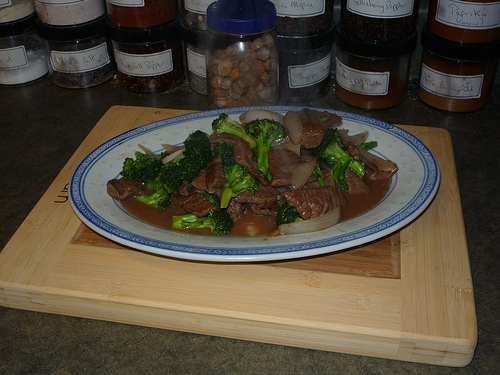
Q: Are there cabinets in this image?
A: No, there are no cabinets.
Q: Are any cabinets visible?
A: No, there are no cabinets.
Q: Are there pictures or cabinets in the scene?
A: No, there are no cabinets or pictures.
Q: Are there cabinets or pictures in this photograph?
A: No, there are no cabinets or pictures.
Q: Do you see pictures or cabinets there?
A: No, there are no cabinets or pictures.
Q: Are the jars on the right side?
A: Yes, the jars are on the right of the image.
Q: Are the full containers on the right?
A: Yes, the jars are on the right of the image.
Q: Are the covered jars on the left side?
A: No, the jars are on the right of the image.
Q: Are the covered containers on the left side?
A: No, the jars are on the right of the image.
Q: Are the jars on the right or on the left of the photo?
A: The jars are on the right of the image.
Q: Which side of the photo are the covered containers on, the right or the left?
A: The jars are on the right of the image.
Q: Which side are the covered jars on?
A: The jars are on the right of the image.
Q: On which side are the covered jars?
A: The jars are on the right of the image.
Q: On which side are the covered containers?
A: The jars are on the right of the image.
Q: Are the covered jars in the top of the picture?
A: Yes, the jars are in the top of the image.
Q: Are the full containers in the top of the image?
A: Yes, the jars are in the top of the image.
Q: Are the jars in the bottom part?
A: No, the jars are in the top of the image.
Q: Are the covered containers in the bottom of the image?
A: No, the jars are in the top of the image.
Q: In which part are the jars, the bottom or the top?
A: The jars are in the top of the image.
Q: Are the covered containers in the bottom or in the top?
A: The jars are in the top of the image.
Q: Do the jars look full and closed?
A: Yes, the jars are full and closed.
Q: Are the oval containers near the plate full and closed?
A: Yes, the jars are full and closed.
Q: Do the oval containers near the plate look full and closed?
A: Yes, the jars are full and closed.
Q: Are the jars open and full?
A: No, the jars are full but closed.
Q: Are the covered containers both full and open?
A: No, the jars are full but closed.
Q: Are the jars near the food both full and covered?
A: Yes, the jars are full and covered.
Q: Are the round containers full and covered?
A: Yes, the jars are full and covered.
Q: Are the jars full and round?
A: Yes, the jars are full and round.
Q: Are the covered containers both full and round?
A: Yes, the jars are full and round.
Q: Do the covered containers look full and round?
A: Yes, the jars are full and round.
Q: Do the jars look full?
A: Yes, the jars are full.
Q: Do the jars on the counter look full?
A: Yes, the jars are full.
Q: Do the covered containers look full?
A: Yes, the jars are full.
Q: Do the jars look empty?
A: No, the jars are full.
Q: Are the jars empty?
A: No, the jars are full.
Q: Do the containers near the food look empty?
A: No, the jars are full.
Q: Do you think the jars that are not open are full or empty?
A: The jars are full.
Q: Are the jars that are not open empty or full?
A: The jars are full.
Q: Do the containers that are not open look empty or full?
A: The jars are full.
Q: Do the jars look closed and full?
A: Yes, the jars are closed and full.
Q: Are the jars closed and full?
A: Yes, the jars are closed and full.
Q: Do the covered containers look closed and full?
A: Yes, the jars are closed and full.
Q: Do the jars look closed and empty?
A: No, the jars are closed but full.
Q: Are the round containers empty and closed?
A: No, the jars are closed but full.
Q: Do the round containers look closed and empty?
A: No, the jars are closed but full.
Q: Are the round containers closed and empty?
A: No, the jars are closed but full.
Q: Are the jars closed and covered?
A: Yes, the jars are closed and covered.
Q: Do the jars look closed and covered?
A: Yes, the jars are closed and covered.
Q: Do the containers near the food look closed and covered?
A: Yes, the jars are closed and covered.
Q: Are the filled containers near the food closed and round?
A: Yes, the jars are closed and round.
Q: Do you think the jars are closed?
A: Yes, the jars are closed.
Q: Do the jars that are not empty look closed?
A: Yes, the jars are closed.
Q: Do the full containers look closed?
A: Yes, the jars are closed.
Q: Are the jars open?
A: No, the jars are closed.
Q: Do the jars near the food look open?
A: No, the jars are closed.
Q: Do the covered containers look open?
A: No, the jars are closed.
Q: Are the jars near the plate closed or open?
A: The jars are closed.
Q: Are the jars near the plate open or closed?
A: The jars are closed.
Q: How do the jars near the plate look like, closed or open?
A: The jars are closed.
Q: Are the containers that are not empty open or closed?
A: The jars are closed.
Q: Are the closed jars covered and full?
A: Yes, the jars are covered and full.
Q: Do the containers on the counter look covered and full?
A: Yes, the jars are covered and full.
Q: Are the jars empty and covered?
A: No, the jars are covered but full.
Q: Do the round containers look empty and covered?
A: No, the jars are covered but full.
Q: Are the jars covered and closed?
A: Yes, the jars are covered and closed.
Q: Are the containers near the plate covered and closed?
A: Yes, the jars are covered and closed.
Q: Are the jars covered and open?
A: No, the jars are covered but closed.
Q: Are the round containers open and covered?
A: No, the jars are covered but closed.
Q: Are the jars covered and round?
A: Yes, the jars are covered and round.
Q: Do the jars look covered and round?
A: Yes, the jars are covered and round.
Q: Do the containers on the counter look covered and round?
A: Yes, the jars are covered and round.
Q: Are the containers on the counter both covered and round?
A: Yes, the jars are covered and round.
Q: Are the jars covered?
A: Yes, the jars are covered.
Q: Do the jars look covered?
A: Yes, the jars are covered.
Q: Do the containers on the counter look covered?
A: Yes, the jars are covered.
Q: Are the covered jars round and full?
A: Yes, the jars are round and full.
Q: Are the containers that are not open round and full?
A: Yes, the jars are round and full.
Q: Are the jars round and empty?
A: No, the jars are round but full.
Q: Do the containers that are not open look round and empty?
A: No, the jars are round but full.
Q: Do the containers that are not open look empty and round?
A: No, the jars are round but full.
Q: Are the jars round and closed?
A: Yes, the jars are round and closed.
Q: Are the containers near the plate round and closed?
A: Yes, the jars are round and closed.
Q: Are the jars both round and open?
A: No, the jars are round but closed.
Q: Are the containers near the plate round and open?
A: No, the jars are round but closed.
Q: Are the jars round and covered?
A: Yes, the jars are round and covered.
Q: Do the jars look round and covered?
A: Yes, the jars are round and covered.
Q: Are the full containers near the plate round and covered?
A: Yes, the jars are round and covered.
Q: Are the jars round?
A: Yes, the jars are round.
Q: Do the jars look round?
A: Yes, the jars are round.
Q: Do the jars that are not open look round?
A: Yes, the jars are round.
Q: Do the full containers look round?
A: Yes, the jars are round.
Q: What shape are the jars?
A: The jars are round.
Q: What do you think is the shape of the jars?
A: The jars are round.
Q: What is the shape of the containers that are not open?
A: The jars are round.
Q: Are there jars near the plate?
A: Yes, there are jars near the plate.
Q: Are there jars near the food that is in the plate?
A: Yes, there are jars near the food.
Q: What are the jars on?
A: The jars are on the counter.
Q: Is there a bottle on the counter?
A: No, there are jars on the counter.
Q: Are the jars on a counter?
A: Yes, the jars are on a counter.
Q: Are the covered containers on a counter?
A: Yes, the jars are on a counter.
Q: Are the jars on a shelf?
A: No, the jars are on a counter.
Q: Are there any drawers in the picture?
A: No, there are no drawers.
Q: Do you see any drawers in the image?
A: No, there are no drawers.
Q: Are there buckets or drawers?
A: No, there are no drawers or buckets.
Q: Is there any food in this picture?
A: Yes, there is food.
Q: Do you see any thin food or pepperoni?
A: Yes, there is thin food.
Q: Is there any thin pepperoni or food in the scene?
A: Yes, there is thin food.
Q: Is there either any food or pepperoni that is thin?
A: Yes, the food is thin.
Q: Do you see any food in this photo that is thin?
A: Yes, there is thin food.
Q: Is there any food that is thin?
A: Yes, there is food that is thin.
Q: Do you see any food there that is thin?
A: Yes, there is food that is thin.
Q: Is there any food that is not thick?
A: Yes, there is thin food.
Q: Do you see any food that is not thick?
A: Yes, there is thin food.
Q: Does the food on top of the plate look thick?
A: No, the food is thin.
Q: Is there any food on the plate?
A: Yes, there is food on the plate.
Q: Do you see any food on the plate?
A: Yes, there is food on the plate.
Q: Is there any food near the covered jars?
A: Yes, there is food near the jars.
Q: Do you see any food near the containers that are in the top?
A: Yes, there is food near the jars.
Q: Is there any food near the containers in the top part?
A: Yes, there is food near the jars.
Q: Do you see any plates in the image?
A: Yes, there is a plate.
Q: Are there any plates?
A: Yes, there is a plate.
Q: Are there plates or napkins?
A: Yes, there is a plate.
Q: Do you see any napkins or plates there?
A: Yes, there is a plate.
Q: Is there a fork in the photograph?
A: No, there are no forks.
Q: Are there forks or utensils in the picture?
A: No, there are no forks or utensils.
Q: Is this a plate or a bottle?
A: This is a plate.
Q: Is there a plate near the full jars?
A: Yes, there is a plate near the jars.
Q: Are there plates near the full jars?
A: Yes, there is a plate near the jars.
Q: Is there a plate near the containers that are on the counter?
A: Yes, there is a plate near the jars.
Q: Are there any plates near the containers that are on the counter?
A: Yes, there is a plate near the jars.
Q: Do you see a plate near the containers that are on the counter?
A: Yes, there is a plate near the jars.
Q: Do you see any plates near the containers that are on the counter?
A: Yes, there is a plate near the jars.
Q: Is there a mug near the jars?
A: No, there is a plate near the jars.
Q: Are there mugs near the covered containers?
A: No, there is a plate near the jars.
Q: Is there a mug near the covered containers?
A: No, there is a plate near the jars.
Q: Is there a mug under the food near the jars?
A: No, there is a plate under the food.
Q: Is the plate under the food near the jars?
A: Yes, the plate is under the food.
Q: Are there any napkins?
A: No, there are no napkins.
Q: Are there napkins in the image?
A: No, there are no napkins.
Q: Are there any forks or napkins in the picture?
A: No, there are no napkins or forks.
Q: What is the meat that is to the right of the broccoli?
A: The meat is beef.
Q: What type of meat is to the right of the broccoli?
A: The meat is beef.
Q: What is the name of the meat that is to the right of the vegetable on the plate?
A: The meat is beef.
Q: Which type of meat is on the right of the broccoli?
A: The meat is beef.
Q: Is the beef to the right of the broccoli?
A: Yes, the beef is to the right of the broccoli.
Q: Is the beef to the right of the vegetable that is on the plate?
A: Yes, the beef is to the right of the broccoli.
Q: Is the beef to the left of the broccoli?
A: No, the beef is to the right of the broccoli.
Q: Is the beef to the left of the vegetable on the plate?
A: No, the beef is to the right of the broccoli.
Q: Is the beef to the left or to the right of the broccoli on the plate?
A: The beef is to the right of the broccoli.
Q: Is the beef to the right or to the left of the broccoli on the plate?
A: The beef is to the right of the broccoli.